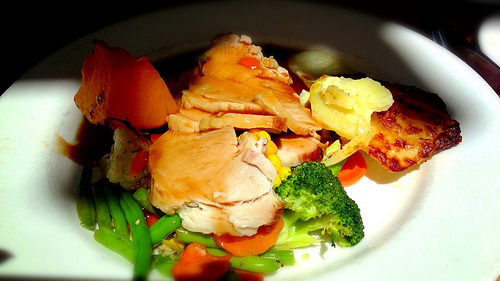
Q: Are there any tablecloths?
A: No, there are no tablecloths.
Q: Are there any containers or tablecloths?
A: No, there are no tablecloths or containers.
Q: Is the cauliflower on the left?
A: Yes, the cauliflower is on the left of the image.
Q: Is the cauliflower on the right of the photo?
A: No, the cauliflower is on the left of the image.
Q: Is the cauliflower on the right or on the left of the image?
A: The cauliflower is on the left of the image.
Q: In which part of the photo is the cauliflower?
A: The cauliflower is on the left of the image.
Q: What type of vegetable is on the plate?
A: The vegetable is cauliflower.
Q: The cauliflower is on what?
A: The cauliflower is on the plate.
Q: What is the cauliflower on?
A: The cauliflower is on the plate.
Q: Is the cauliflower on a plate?
A: Yes, the cauliflower is on a plate.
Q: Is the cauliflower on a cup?
A: No, the cauliflower is on a plate.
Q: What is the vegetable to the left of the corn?
A: The vegetable is cauliflower.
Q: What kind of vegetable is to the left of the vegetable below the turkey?
A: The vegetable is cauliflower.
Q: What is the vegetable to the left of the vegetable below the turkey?
A: The vegetable is cauliflower.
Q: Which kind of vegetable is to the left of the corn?
A: The vegetable is cauliflower.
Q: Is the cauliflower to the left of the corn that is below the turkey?
A: Yes, the cauliflower is to the left of the corn.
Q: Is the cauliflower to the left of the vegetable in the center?
A: Yes, the cauliflower is to the left of the corn.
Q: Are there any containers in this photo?
A: No, there are no containers.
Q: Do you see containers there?
A: No, there are no containers.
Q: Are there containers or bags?
A: No, there are no containers or bags.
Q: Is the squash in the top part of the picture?
A: Yes, the squash is in the top of the image.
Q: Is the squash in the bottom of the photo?
A: No, the squash is in the top of the image.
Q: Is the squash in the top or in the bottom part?
A: The squash is in the top of the image.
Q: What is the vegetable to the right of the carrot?
A: The vegetable is a squash.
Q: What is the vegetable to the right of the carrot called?
A: The vegetable is a squash.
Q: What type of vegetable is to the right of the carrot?
A: The vegetable is a squash.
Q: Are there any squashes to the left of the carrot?
A: No, the squash is to the right of the carrot.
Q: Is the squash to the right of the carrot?
A: Yes, the squash is to the right of the carrot.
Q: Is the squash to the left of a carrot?
A: No, the squash is to the right of a carrot.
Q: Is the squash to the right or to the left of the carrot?
A: The squash is to the right of the carrot.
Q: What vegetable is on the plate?
A: The vegetable is a squash.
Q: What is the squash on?
A: The squash is on the plate.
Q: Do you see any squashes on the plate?
A: Yes, there is a squash on the plate.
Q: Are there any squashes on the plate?
A: Yes, there is a squash on the plate.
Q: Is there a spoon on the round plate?
A: No, there is a squash on the plate.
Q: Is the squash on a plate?
A: Yes, the squash is on a plate.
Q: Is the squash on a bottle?
A: No, the squash is on a plate.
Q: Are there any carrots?
A: Yes, there is a carrot.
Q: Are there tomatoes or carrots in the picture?
A: Yes, there is a carrot.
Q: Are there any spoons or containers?
A: No, there are no spoons or containers.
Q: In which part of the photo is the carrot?
A: The carrot is on the left of the image.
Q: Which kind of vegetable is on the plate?
A: The vegetable is a carrot.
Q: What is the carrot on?
A: The carrot is on the plate.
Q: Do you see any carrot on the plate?
A: Yes, there is a carrot on the plate.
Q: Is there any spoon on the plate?
A: No, there is a carrot on the plate.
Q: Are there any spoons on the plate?
A: No, there is a carrot on the plate.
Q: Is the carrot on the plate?
A: Yes, the carrot is on the plate.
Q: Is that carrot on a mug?
A: No, the carrot is on the plate.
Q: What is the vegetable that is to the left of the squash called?
A: The vegetable is a carrot.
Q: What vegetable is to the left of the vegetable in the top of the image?
A: The vegetable is a carrot.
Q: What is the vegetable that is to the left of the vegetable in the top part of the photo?
A: The vegetable is a carrot.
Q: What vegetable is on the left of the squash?
A: The vegetable is a carrot.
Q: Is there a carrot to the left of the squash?
A: Yes, there is a carrot to the left of the squash.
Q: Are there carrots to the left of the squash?
A: Yes, there is a carrot to the left of the squash.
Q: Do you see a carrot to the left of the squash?
A: Yes, there is a carrot to the left of the squash.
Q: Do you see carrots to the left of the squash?
A: Yes, there is a carrot to the left of the squash.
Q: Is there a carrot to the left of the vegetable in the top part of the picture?
A: Yes, there is a carrot to the left of the squash.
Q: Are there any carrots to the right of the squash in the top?
A: No, the carrot is to the left of the squash.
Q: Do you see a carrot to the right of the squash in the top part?
A: No, the carrot is to the left of the squash.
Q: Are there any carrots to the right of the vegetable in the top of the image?
A: No, the carrot is to the left of the squash.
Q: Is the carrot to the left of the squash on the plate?
A: Yes, the carrot is to the left of the squash.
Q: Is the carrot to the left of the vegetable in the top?
A: Yes, the carrot is to the left of the squash.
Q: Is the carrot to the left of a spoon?
A: No, the carrot is to the left of the squash.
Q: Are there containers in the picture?
A: No, there are no containers.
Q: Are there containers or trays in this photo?
A: No, there are no containers or trays.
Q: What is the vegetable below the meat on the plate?
A: The vegetable is corn.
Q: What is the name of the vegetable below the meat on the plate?
A: The vegetable is corn.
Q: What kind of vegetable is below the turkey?
A: The vegetable is corn.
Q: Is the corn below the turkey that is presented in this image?
A: Yes, the corn is below the turkey.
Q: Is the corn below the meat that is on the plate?
A: Yes, the corn is below the turkey.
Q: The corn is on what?
A: The corn is on the plate.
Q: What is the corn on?
A: The corn is on the plate.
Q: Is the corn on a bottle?
A: No, the corn is on the plate.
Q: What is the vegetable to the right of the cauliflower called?
A: The vegetable is corn.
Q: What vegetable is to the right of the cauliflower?
A: The vegetable is corn.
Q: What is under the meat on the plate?
A: The corn is under the turkey.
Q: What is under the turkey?
A: The corn is under the turkey.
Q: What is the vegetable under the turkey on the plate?
A: The vegetable is corn.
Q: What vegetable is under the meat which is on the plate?
A: The vegetable is corn.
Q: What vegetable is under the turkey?
A: The vegetable is corn.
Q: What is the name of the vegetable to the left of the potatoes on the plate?
A: The vegetable is corn.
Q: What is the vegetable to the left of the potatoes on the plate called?
A: The vegetable is corn.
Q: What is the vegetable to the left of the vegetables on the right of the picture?
A: The vegetable is corn.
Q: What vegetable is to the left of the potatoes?
A: The vegetable is corn.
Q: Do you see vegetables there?
A: Yes, there are vegetables.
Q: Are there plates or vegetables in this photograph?
A: Yes, there are vegetables.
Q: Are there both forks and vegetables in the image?
A: Yes, there are both vegetables and a fork.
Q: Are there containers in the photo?
A: No, there are no containers.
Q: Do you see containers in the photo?
A: No, there are no containers.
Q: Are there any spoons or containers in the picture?
A: No, there are no containers or spoons.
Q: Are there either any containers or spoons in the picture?
A: No, there are no containers or spoons.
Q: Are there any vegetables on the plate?
A: Yes, there are vegetables on the plate.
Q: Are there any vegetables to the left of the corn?
A: Yes, there are vegetables to the left of the corn.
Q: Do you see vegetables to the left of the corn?
A: Yes, there are vegetables to the left of the corn.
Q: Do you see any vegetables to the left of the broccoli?
A: Yes, there are vegetables to the left of the broccoli.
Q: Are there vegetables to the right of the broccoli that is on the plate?
A: No, the vegetables are to the left of the broccoli.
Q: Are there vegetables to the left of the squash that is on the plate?
A: Yes, there are vegetables to the left of the squash.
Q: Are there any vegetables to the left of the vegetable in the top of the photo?
A: Yes, there are vegetables to the left of the squash.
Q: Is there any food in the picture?
A: Yes, there is food.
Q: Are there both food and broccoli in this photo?
A: Yes, there are both food and broccoli.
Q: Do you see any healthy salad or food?
A: Yes, there is healthy food.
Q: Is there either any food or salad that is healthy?
A: Yes, the food is healthy.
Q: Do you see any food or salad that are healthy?
A: Yes, the food is healthy.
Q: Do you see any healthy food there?
A: Yes, there is healthy food.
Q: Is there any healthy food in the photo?
A: Yes, there is healthy food.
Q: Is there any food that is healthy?
A: Yes, there is food that is healthy.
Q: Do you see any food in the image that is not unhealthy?
A: Yes, there is healthy food.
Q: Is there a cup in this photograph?
A: No, there are no cups.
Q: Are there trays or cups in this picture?
A: No, there are no cups or trays.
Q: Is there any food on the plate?
A: Yes, there is food on the plate.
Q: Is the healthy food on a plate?
A: Yes, the food is on a plate.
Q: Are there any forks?
A: Yes, there is a fork.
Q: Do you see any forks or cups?
A: Yes, there is a fork.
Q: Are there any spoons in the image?
A: No, there are no spoons.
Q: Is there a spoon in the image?
A: No, there are no spoons.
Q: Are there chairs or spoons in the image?
A: No, there are no spoons or chairs.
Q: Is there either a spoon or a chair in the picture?
A: No, there are no spoons or chairs.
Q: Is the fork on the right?
A: Yes, the fork is on the right of the image.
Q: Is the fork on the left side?
A: No, the fork is on the right of the image.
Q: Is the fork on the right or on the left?
A: The fork is on the right of the image.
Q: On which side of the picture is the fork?
A: The fork is on the right of the image.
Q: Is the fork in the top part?
A: Yes, the fork is in the top of the image.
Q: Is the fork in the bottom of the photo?
A: No, the fork is in the top of the image.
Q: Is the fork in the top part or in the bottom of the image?
A: The fork is in the top of the image.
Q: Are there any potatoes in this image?
A: Yes, there are potatoes.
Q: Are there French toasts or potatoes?
A: Yes, there are potatoes.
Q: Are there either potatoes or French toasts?
A: Yes, there are potatoes.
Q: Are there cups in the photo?
A: No, there are no cups.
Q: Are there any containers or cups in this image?
A: No, there are no cups or containers.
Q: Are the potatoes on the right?
A: Yes, the potatoes are on the right of the image.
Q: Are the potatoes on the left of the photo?
A: No, the potatoes are on the right of the image.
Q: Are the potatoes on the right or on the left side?
A: The potatoes are on the right of the image.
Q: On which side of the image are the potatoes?
A: The potatoes are on the right of the image.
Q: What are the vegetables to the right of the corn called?
A: The vegetables are potatoes.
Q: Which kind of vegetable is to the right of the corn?
A: The vegetables are potatoes.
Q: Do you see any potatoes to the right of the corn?
A: Yes, there are potatoes to the right of the corn.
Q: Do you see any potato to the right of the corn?
A: Yes, there are potatoes to the right of the corn.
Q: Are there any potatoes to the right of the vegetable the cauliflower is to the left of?
A: Yes, there are potatoes to the right of the corn.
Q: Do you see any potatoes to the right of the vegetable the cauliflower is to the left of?
A: Yes, there are potatoes to the right of the corn.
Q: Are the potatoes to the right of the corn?
A: Yes, the potatoes are to the right of the corn.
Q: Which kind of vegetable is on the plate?
A: The vegetables are potatoes.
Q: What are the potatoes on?
A: The potatoes are on the plate.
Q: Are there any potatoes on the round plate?
A: Yes, there are potatoes on the plate.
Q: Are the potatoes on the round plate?
A: Yes, the potatoes are on the plate.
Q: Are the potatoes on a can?
A: No, the potatoes are on the plate.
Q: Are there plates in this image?
A: Yes, there is a plate.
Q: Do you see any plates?
A: Yes, there is a plate.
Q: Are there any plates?
A: Yes, there is a plate.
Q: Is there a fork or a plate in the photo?
A: Yes, there is a plate.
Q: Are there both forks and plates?
A: Yes, there are both a plate and a fork.